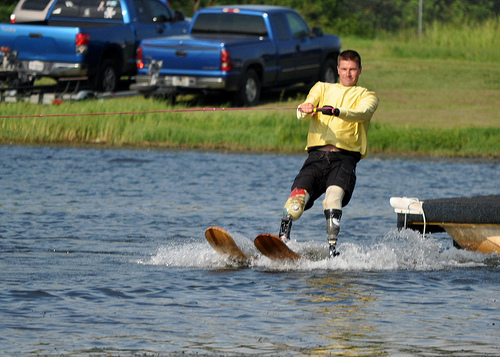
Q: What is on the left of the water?
A: A blue truck.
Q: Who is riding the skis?
A: A man with no legs.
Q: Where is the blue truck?
A: Parked.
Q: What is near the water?
A: The dock.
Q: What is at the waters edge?
A: Green grass.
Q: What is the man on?
A: Water skis.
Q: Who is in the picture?
A: A man with prosthetic legs.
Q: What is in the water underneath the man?
A: Two skis.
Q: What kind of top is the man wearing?
A: A yellow top.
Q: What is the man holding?
A: Red rope.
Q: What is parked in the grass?
A: A blue pick-up truck.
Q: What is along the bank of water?
A: Grass.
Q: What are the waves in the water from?
A: The skier.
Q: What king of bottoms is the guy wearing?
A: Black swim trunks.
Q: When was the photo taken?
A: Daytime.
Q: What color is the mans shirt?
A: Yellow.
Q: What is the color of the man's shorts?
A: Black.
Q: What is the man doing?
A: Water skiing.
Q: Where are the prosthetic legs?
A: On the man.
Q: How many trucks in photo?
A: Two.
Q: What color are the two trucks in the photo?
A: Blue.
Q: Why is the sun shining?
A: It is day time.